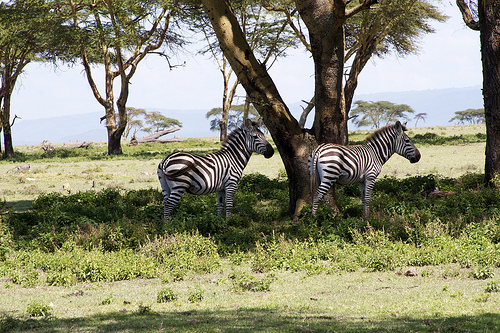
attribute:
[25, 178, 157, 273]
grass — long , green, brown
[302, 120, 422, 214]
zebra — black, white, striped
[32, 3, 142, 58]
green leaves — lush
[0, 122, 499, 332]
grass — green, long, brown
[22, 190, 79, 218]
grass — brown, long, green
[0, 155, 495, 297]
grass — long, brown, green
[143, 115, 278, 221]
zebra — black, white, striped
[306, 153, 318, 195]
tail — black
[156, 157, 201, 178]
tail — black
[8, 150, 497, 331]
grass — brown, long, green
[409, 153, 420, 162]
nose — brown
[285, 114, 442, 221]
zebra — walking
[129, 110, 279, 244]
zebra — walking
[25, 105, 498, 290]
grass — green, brown, long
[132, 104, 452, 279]
zebras — black, white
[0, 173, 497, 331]
grass — green, long, brown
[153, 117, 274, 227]
zebras — in line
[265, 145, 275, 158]
nose — black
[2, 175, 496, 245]
shade — cool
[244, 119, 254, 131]
ear — zebra ear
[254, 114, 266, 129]
ear — zebra ear